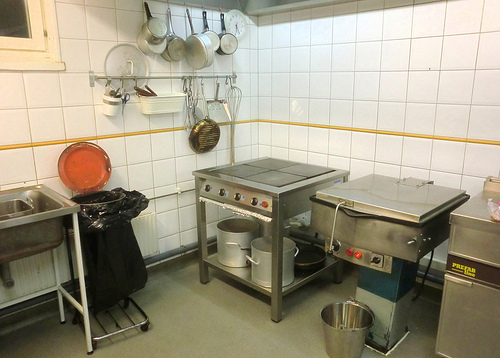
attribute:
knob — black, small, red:
[364, 255, 395, 272]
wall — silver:
[74, 14, 263, 142]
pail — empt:
[298, 292, 408, 356]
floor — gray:
[87, 283, 406, 352]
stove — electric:
[292, 163, 470, 341]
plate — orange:
[52, 106, 130, 214]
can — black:
[74, 184, 161, 308]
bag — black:
[82, 181, 162, 253]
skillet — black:
[187, 84, 220, 172]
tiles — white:
[323, 22, 467, 84]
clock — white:
[216, 10, 263, 41]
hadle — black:
[130, 5, 160, 22]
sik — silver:
[0, 171, 90, 357]